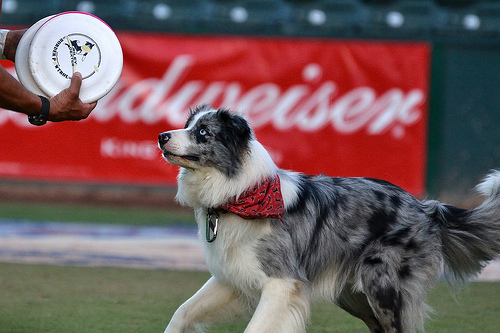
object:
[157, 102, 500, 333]
dog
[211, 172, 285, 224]
scarf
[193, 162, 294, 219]
neck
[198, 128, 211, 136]
eye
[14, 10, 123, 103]
frisbie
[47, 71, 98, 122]
hand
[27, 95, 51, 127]
watch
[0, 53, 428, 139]
budweiser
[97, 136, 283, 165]
sign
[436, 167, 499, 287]
tail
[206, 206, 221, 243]
lock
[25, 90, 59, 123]
wrist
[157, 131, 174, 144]
nose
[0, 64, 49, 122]
arm